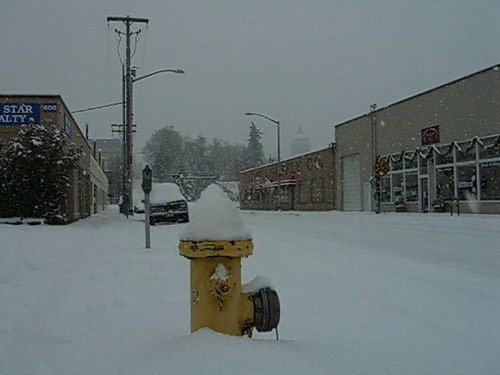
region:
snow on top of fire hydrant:
[192, 176, 248, 256]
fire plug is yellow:
[187, 237, 273, 360]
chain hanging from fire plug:
[270, 321, 288, 359]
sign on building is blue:
[0, 105, 57, 142]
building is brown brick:
[8, 93, 115, 222]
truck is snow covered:
[145, 174, 186, 226]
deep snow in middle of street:
[206, 183, 477, 374]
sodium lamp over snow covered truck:
[135, 48, 207, 79]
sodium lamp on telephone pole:
[97, 17, 165, 94]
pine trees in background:
[147, 116, 262, 190]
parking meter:
[133, 163, 159, 248]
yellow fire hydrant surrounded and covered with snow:
[174, 181, 283, 371]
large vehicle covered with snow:
[146, 181, 188, 225]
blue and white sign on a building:
[2, 102, 42, 124]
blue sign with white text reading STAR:
[3, 102, 35, 114]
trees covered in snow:
[0, 118, 90, 222]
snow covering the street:
[244, 208, 499, 372]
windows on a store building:
[370, 133, 495, 204]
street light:
[130, 67, 194, 84]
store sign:
[416, 123, 444, 145]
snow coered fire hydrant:
[175, 181, 315, 369]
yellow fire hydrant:
[149, 171, 308, 353]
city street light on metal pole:
[235, 91, 291, 233]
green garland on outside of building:
[362, 136, 497, 238]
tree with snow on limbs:
[5, 108, 103, 265]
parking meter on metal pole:
[133, 151, 161, 258]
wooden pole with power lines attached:
[102, 10, 154, 230]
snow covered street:
[284, 223, 459, 373]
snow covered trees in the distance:
[153, 106, 258, 189]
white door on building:
[327, 134, 382, 248]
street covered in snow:
[16, 78, 478, 361]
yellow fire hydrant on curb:
[166, 177, 300, 344]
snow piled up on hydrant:
[171, 175, 279, 257]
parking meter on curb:
[128, 151, 163, 250]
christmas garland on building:
[374, 136, 499, 166]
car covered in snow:
[143, 175, 212, 232]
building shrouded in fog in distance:
[277, 113, 314, 161]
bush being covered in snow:
[8, 111, 85, 237]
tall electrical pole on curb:
[97, 12, 197, 217]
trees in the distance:
[145, 121, 287, 204]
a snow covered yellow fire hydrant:
[174, 185, 279, 339]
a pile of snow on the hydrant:
[185, 184, 250, 239]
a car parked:
[147, 179, 187, 223]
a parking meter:
[140, 164, 157, 246]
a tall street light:
[127, 61, 185, 214]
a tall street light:
[246, 107, 286, 208]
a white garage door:
[340, 153, 367, 206]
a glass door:
[417, 174, 432, 208]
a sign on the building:
[420, 124, 442, 139]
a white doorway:
[363, 178, 372, 210]